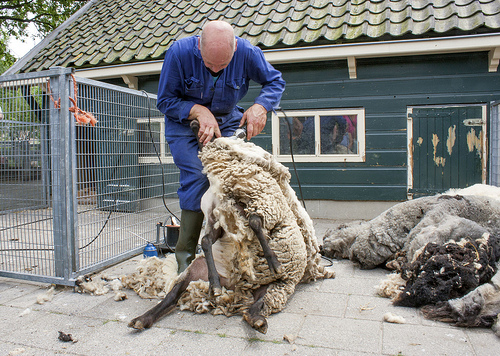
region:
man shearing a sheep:
[126, 22, 326, 338]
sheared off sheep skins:
[330, 190, 495, 332]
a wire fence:
[1, 71, 172, 286]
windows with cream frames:
[121, 91, 373, 161]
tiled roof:
[5, 5, 490, 87]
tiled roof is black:
[10, 5, 495, 70]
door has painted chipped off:
[400, 101, 487, 197]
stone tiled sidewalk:
[0, 210, 491, 351]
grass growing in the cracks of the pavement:
[155, 305, 278, 352]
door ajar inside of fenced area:
[92, 120, 147, 215]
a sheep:
[179, 128, 312, 331]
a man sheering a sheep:
[165, 17, 330, 320]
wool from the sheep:
[357, 203, 475, 279]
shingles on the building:
[51, 0, 495, 42]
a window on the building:
[277, 112, 360, 157]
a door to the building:
[411, 110, 476, 191]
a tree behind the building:
[1, 2, 54, 65]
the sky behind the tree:
[4, 25, 35, 51]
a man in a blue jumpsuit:
[154, 20, 288, 285]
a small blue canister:
[126, 229, 160, 258]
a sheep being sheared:
[123, 118, 332, 335]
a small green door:
[402, 102, 488, 198]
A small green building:
[0, 0, 499, 206]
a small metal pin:
[0, 63, 194, 285]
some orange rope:
[46, 74, 101, 131]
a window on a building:
[269, 110, 367, 160]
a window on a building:
[134, 115, 173, 161]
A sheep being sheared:
[121, 135, 331, 330]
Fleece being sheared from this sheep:
[110, 135, 335, 310]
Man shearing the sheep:
[155, 16, 285, 271]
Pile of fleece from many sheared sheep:
[317, 181, 497, 333]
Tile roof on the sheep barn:
[12, 0, 497, 80]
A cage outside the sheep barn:
[0, 65, 180, 285]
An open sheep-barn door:
[45, 115, 135, 210]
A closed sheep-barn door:
[405, 105, 485, 200]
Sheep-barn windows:
[136, 106, 362, 158]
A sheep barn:
[1, 0, 498, 219]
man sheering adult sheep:
[112, 8, 370, 348]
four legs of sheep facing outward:
[123, 168, 314, 338]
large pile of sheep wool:
[316, 163, 498, 348]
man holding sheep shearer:
[226, 110, 273, 160]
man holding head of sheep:
[153, 74, 276, 158]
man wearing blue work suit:
[148, 16, 310, 295]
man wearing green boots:
[158, 190, 283, 293]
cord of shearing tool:
[258, 92, 323, 259]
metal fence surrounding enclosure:
[11, 61, 188, 287]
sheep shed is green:
[59, 7, 498, 216]